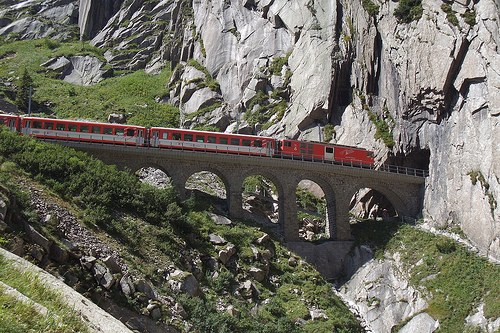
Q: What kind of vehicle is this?
A: Train.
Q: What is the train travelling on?
A: Train tracks.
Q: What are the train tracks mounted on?
A: Bridge.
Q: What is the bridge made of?
A: Stone.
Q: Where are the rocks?
A: On the side of hill.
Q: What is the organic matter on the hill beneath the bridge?
A: Grass.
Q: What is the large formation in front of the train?
A: Rock mountain.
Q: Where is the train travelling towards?
A: Tunnel.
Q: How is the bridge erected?
A: Stone pillars.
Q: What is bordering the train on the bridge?
A: Fence.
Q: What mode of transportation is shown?
A: Train.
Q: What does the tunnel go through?
A: Rock.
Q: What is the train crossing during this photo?
A: Bridge.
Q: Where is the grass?
A: Growing on some of the rocks.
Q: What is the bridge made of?
A: Concrete.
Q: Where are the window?
A: Train.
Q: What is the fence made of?
A: Metal.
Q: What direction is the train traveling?
A: To the left.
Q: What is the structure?
A: A bridge.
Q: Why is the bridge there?
A: For the train.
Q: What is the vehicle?
A: The train.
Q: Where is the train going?
A: Through a tunnel.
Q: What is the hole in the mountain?
A: A tunnel.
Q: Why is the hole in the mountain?
A: So the train can pass through.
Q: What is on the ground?
A: Grass.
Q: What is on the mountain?
A: Trees.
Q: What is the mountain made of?
A: Stone.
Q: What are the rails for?
A: Safety.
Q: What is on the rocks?
A: Grass.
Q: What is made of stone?
A: The bridge.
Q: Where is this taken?
A: Mountain.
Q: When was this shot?
A: Daytime.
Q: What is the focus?
A: Train going into mountain tunnel.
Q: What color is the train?
A: Red and grey.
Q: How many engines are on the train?
A: 1.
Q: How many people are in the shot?
A: 0.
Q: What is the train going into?
A: Tunnel.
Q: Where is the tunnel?
A: Mountain.